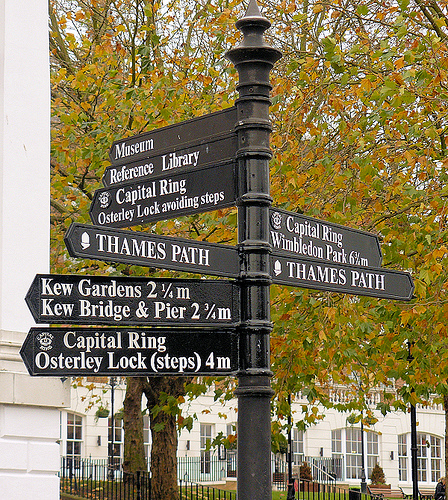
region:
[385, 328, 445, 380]
leaves on the tree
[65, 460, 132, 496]
plack gate around building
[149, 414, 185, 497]
bark of tree in front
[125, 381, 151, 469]
bark of the tree in back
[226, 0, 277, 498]
black pole for street signs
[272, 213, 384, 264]
black and white sign for capital ring wimbeldon park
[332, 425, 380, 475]
windows on the building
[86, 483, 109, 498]
leaves on the ground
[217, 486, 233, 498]
green grass on the ground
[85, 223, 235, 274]
black and white sign for thames path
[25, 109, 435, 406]
Black and white direction signs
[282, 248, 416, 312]
Thames path direction sign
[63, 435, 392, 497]
Black fence around the building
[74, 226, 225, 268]
White lettering on black sign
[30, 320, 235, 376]
Capital ring sign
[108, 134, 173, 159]
Museum sign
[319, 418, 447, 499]
Two large clear windows on the building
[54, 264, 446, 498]
White building in the background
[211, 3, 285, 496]
Tall skinny black pointy pole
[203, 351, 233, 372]
4m writing on black sign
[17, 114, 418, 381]
black signs with white text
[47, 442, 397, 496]
metal gates on the ground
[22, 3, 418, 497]
a fancy black street sign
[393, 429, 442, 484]
windows on a white building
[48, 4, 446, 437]
leaves on a tree about to change color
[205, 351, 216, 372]
the number 4 on a sign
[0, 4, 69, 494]
white corner of a building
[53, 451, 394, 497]
black fencing on the ground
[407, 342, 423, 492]
black light post in the garden area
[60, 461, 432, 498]
garden area in front of the building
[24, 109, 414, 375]
a pole with many street signs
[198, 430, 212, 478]
a window in the building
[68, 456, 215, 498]
a black fence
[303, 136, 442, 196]
the yellow and green leaves on the tree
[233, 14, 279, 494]
the black pole of the street sign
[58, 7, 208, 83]
the sky through the trees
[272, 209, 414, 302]
two street signs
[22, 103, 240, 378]
street signs on arrows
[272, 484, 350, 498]
grass in front of the building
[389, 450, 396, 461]
a light on the building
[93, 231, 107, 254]
the letter T on a sign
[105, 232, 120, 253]
the letter H on a sign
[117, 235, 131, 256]
the letter A on a sign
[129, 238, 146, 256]
the letter M on a sign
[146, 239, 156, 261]
the letter E on a sign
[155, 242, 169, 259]
the letter S on a sign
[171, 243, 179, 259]
the letter P on a sign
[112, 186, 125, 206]
the letter C on a sign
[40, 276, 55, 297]
the letter K on a sign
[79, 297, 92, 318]
the letter B on a sign